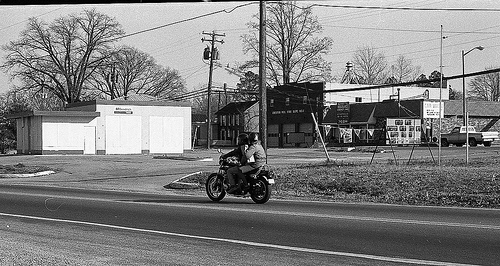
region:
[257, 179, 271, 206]
part of a wheel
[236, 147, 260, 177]
part of a short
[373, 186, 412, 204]
edge of a road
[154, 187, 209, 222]
part of a shade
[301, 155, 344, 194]
part of a ground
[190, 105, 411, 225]
the man is riding motorcycle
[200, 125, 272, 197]
the man is riding motorcycle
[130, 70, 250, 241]
the man is riding motorcycle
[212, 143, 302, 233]
the man is riding motorcycle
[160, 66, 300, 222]
the man is riding motorcycle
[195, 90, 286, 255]
the man is riding motorcycle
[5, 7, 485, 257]
a black and white photo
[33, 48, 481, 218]
this picture was probably taken during the 50s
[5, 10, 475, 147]
this picture was taken during the fall or early winter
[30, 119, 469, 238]
two motorcycle riders on the street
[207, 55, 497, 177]
scenery from a small town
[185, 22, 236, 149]
a utlity pole in the picture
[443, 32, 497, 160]
a street light near the road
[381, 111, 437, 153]
a sign that cannot be read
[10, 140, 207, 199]
a parking lot near the street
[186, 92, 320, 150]
buildings on a block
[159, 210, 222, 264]
a white line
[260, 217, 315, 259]
a white line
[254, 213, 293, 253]
a white line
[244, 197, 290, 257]
a white line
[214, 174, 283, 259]
a white line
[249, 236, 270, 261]
a white line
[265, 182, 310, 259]
a white line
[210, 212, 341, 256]
the road is clear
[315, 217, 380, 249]
the road is clear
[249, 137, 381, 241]
the road is clear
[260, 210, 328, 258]
the road is clear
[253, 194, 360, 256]
the road is clear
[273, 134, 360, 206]
the road is clear